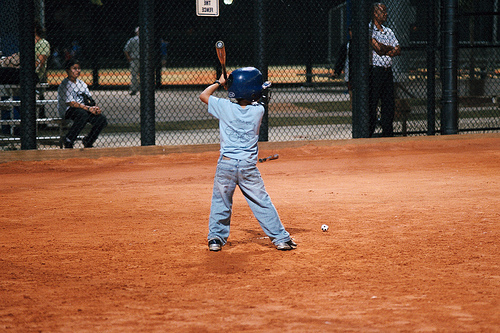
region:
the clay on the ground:
[97, 179, 157, 257]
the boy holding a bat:
[203, 24, 297, 274]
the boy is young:
[201, 35, 312, 277]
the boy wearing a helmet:
[214, 46, 314, 276]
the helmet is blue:
[221, 65, 288, 105]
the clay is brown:
[36, 207, 130, 268]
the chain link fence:
[55, 12, 487, 133]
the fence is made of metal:
[36, 12, 496, 144]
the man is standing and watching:
[358, 0, 415, 142]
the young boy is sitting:
[42, 58, 129, 155]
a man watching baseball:
[350, 4, 411, 134]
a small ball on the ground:
[306, 208, 348, 251]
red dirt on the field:
[38, 175, 154, 276]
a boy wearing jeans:
[195, 141, 308, 251]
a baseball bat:
[207, 31, 237, 100]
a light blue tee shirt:
[195, 85, 290, 157]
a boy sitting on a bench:
[34, 50, 124, 161]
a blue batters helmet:
[220, 57, 279, 104]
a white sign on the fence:
[187, 0, 235, 21]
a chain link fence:
[47, 17, 138, 119]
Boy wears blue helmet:
[227, 64, 268, 101]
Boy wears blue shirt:
[214, 106, 249, 145]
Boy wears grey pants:
[219, 169, 264, 214]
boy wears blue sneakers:
[201, 234, 231, 256]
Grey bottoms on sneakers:
[208, 244, 224, 250]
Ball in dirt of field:
[316, 212, 337, 242]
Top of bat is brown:
[205, 34, 240, 71]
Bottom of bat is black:
[217, 67, 234, 82]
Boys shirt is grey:
[61, 82, 78, 97]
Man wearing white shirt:
[371, 53, 385, 69]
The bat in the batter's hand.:
[207, 40, 229, 83]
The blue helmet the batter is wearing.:
[218, 65, 268, 96]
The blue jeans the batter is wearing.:
[205, 152, 287, 247]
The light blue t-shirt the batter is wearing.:
[210, 92, 261, 159]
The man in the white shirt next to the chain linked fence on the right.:
[362, 12, 403, 68]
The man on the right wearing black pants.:
[376, 60, 401, 132]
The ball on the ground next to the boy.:
[317, 220, 334, 233]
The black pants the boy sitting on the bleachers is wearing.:
[65, 102, 104, 141]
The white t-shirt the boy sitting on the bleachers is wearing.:
[62, 75, 90, 105]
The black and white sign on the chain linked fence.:
[194, 2, 222, 22]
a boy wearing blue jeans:
[206, 147, 301, 262]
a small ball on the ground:
[312, 214, 338, 241]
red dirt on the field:
[42, 216, 144, 301]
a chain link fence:
[52, 37, 124, 68]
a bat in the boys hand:
[197, 35, 241, 91]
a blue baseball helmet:
[215, 55, 281, 119]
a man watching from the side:
[355, 0, 422, 138]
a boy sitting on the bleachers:
[42, 47, 120, 150]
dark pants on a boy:
[59, 98, 113, 149]